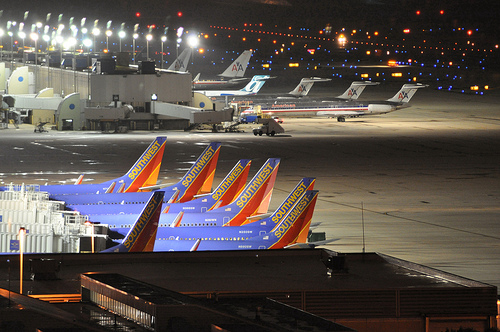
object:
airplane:
[235, 80, 432, 124]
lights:
[313, 64, 319, 70]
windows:
[213, 222, 217, 225]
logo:
[347, 87, 358, 97]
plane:
[214, 80, 385, 105]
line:
[338, 199, 500, 212]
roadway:
[0, 79, 500, 300]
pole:
[16, 223, 28, 296]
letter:
[273, 230, 282, 239]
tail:
[241, 187, 322, 243]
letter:
[278, 225, 286, 233]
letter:
[281, 221, 289, 230]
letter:
[287, 212, 297, 221]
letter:
[299, 198, 308, 207]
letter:
[253, 175, 264, 185]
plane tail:
[242, 189, 320, 245]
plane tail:
[238, 176, 319, 230]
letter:
[291, 206, 301, 217]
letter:
[280, 203, 289, 211]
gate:
[0, 42, 243, 134]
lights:
[80, 37, 96, 49]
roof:
[0, 244, 500, 324]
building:
[0, 224, 500, 332]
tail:
[383, 82, 431, 104]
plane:
[251, 117, 285, 138]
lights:
[459, 76, 463, 79]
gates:
[0, 230, 111, 254]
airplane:
[94, 188, 346, 253]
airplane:
[0, 133, 178, 194]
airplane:
[45, 140, 224, 206]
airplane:
[206, 76, 335, 104]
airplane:
[190, 48, 257, 91]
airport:
[0, 0, 500, 332]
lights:
[158, 35, 170, 44]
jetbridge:
[144, 92, 236, 133]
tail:
[96, 134, 168, 186]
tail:
[214, 48, 256, 77]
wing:
[314, 110, 366, 118]